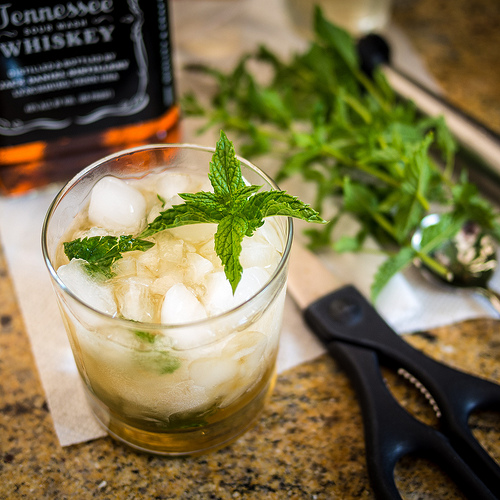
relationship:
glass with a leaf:
[28, 132, 340, 461] [145, 127, 331, 294]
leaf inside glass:
[145, 127, 331, 294] [28, 132, 340, 461]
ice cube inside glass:
[88, 174, 144, 230] [28, 132, 340, 461]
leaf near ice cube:
[145, 127, 331, 294] [88, 174, 144, 230]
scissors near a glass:
[277, 236, 497, 497] [28, 132, 340, 461]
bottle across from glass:
[4, 3, 198, 195] [28, 132, 340, 461]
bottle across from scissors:
[4, 3, 198, 195] [277, 236, 497, 497]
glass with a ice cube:
[28, 132, 340, 461] [88, 174, 144, 230]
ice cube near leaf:
[88, 174, 144, 230] [145, 127, 331, 294]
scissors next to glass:
[277, 236, 497, 497] [28, 132, 340, 461]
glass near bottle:
[28, 132, 340, 461] [4, 3, 198, 195]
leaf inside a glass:
[145, 127, 331, 294] [28, 132, 340, 461]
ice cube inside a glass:
[88, 174, 144, 230] [28, 132, 340, 461]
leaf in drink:
[145, 127, 331, 294] [49, 157, 299, 422]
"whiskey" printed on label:
[3, 32, 123, 60] [0, 16, 171, 109]